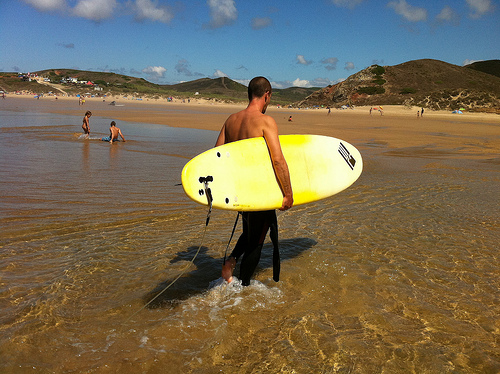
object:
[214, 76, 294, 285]
man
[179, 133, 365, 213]
surfboard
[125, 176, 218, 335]
lanyard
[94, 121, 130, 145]
person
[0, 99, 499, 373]
water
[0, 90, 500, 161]
beach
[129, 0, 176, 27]
cloud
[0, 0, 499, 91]
sky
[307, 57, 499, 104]
hill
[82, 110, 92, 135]
girl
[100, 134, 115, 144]
shorts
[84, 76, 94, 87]
house